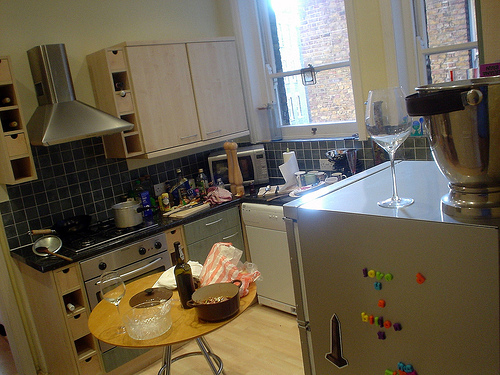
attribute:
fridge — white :
[283, 151, 496, 372]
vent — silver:
[17, 38, 135, 152]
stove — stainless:
[53, 207, 193, 372]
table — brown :
[87, 269, 257, 374]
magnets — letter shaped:
[329, 277, 464, 365]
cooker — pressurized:
[109, 187, 159, 238]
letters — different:
[356, 262, 433, 372]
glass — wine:
[91, 266, 130, 339]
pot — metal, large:
[121, 205, 143, 225]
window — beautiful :
[263, 0, 358, 129]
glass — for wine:
[362, 86, 412, 206]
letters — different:
[359, 262, 424, 374]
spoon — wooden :
[25, 237, 86, 272]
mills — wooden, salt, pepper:
[223, 139, 245, 198]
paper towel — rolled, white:
[277, 146, 302, 191]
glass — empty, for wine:
[98, 268, 130, 337]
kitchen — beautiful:
[1, 0, 498, 372]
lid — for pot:
[181, 271, 251, 326]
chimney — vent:
[32, 93, 109, 133]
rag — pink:
[200, 183, 233, 204]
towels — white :
[277, 149, 304, 190]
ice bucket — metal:
[406, 71, 498, 223]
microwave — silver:
[208, 145, 272, 185]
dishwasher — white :
[244, 202, 299, 314]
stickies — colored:
[360, 262, 426, 372]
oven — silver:
[51, 226, 186, 367]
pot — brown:
[190, 276, 247, 323]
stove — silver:
[56, 199, 189, 375]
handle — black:
[405, 88, 465, 114]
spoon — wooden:
[35, 245, 71, 263]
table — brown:
[85, 259, 256, 371]